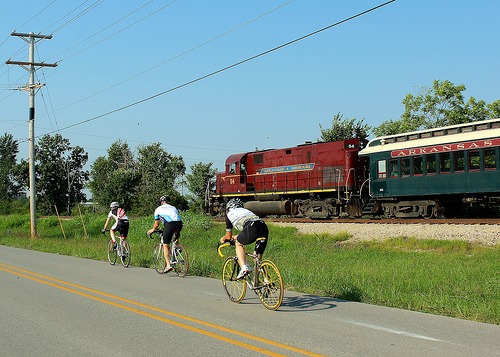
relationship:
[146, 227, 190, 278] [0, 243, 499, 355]
bike are on road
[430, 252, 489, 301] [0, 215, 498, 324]
patch of grass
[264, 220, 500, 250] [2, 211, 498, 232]
gravel beside train tracks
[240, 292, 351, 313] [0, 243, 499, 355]
shadow on pavement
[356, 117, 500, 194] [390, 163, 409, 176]
train car for passengers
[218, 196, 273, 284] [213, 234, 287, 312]
man riding bike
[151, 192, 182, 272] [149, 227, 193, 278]
man riding bike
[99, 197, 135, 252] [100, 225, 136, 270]
man riding bike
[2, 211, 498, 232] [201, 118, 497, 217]
tracks are for train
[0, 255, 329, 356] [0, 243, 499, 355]
lines are on road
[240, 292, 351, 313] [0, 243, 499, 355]
shadow on road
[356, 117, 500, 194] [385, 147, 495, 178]
train car has windows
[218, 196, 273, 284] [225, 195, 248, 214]
rider wearing helmet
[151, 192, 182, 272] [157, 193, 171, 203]
rider wearing helmet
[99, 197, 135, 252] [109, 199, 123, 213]
rider wearing helmet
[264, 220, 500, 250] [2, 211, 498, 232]
gravel beside tracks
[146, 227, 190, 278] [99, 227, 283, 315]
bike riding bikes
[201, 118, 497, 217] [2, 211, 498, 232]
train on train tracks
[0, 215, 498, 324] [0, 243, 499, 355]
grass beside road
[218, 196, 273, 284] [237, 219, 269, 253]
man wearing shorts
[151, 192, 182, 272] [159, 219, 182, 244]
man wearing shorts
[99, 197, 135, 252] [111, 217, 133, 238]
man wearing shorts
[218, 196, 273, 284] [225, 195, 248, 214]
man wearing helmet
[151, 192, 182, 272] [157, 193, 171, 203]
man wearing helmet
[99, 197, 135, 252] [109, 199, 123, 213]
man wearing helmet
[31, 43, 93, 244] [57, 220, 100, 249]
wires used for guiding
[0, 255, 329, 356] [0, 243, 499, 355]
lines on road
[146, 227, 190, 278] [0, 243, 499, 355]
bike on road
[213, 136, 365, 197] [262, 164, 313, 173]
train engine has writing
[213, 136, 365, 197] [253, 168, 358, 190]
train engine has railing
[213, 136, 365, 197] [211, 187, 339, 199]
train engine has stripe